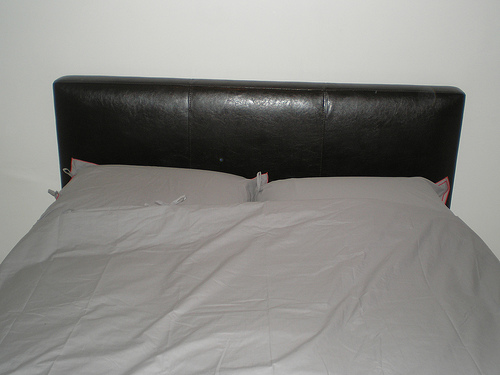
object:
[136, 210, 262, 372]
wrinkles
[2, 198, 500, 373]
bedsheet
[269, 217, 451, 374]
wrinkles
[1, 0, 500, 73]
wall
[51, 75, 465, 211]
head board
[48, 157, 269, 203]
pillow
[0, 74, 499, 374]
bed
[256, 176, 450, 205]
pillow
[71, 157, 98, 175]
corner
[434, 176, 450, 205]
corner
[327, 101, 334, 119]
wrinkle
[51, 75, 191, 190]
section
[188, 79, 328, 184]
section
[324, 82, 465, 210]
section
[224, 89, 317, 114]
reflection